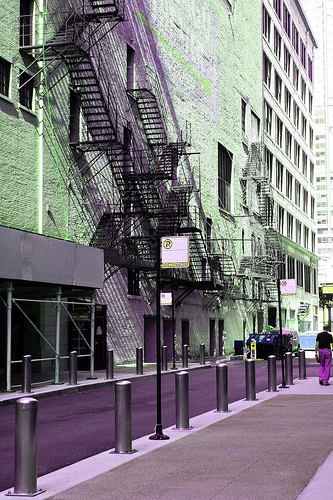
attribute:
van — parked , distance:
[279, 323, 307, 360]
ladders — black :
[27, 14, 232, 310]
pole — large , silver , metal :
[147, 228, 169, 441]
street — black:
[131, 378, 183, 433]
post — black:
[148, 224, 167, 439]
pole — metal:
[152, 269, 174, 442]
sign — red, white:
[156, 235, 192, 276]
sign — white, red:
[158, 287, 175, 310]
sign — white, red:
[272, 274, 300, 303]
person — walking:
[310, 321, 331, 387]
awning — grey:
[20, 219, 123, 292]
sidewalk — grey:
[75, 375, 330, 498]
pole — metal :
[143, 227, 172, 443]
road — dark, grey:
[0, 357, 331, 491]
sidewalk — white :
[0, 0, 320, 390]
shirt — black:
[315, 331, 331, 348]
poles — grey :
[12, 346, 309, 498]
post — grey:
[39, 304, 68, 350]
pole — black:
[149, 228, 165, 445]